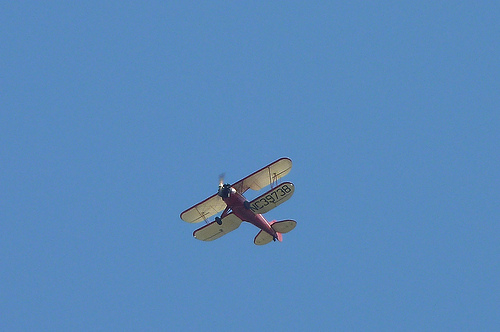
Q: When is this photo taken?
A: Daytime.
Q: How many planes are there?
A: One.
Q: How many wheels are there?
A: Two.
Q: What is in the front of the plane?
A: Propellar.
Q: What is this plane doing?
A: Flying.